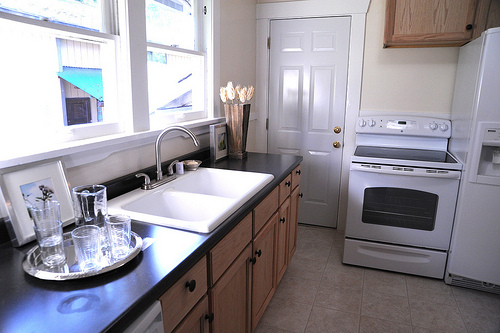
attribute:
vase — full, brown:
[223, 102, 251, 159]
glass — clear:
[103, 208, 135, 257]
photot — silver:
[0, 152, 82, 250]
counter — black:
[1, 140, 303, 328]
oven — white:
[341, 114, 464, 285]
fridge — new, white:
[442, 27, 499, 298]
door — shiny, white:
[267, 15, 353, 231]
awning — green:
[55, 64, 106, 107]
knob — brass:
[332, 141, 342, 150]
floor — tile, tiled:
[254, 223, 499, 330]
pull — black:
[184, 279, 198, 293]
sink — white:
[97, 156, 276, 237]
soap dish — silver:
[179, 157, 204, 172]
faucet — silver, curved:
[154, 124, 201, 182]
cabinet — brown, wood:
[381, 2, 499, 50]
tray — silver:
[18, 224, 145, 285]